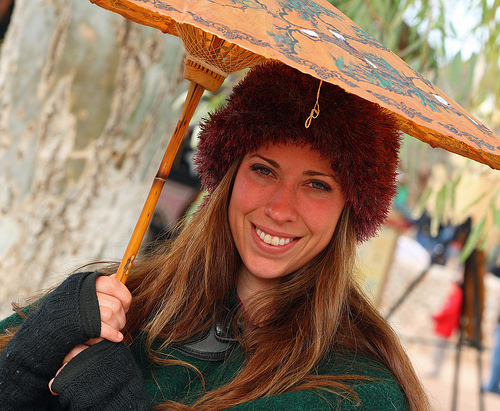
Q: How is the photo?
A: Clear.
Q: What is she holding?
A: Umbrella.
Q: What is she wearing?
A: Hat.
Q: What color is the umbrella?
A: Orange.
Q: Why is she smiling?
A: Happy.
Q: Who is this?
A: Lady.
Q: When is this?
A: Daytime.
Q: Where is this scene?
A: In a park.